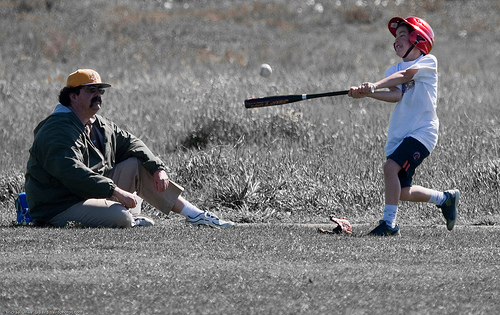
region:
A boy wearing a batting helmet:
[374, 11, 451, 100]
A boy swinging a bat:
[223, 8, 490, 160]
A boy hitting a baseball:
[234, 15, 451, 143]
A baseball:
[249, 48, 302, 95]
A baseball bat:
[217, 85, 390, 145]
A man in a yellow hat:
[44, 45, 174, 171]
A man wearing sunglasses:
[38, 50, 166, 164]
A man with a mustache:
[35, 40, 135, 148]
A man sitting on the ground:
[15, 47, 247, 288]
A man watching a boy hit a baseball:
[29, 2, 476, 274]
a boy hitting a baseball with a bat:
[242, 15, 461, 240]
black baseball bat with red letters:
[241, 82, 377, 110]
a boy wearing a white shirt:
[362, 14, 460, 239]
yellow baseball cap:
[64, 67, 112, 89]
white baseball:
[256, 62, 272, 78]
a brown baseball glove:
[315, 211, 351, 238]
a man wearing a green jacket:
[22, 67, 237, 230]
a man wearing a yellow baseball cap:
[23, 66, 235, 229]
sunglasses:
[82, 84, 104, 96]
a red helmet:
[384, 14, 435, 57]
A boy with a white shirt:
[291, 25, 485, 247]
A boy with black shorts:
[305, 6, 490, 252]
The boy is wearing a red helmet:
[315, 0, 464, 260]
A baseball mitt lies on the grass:
[293, 198, 388, 250]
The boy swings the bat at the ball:
[214, 11, 476, 262]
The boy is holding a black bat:
[231, 17, 474, 252]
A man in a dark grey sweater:
[5, 50, 245, 263]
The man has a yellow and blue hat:
[18, 53, 205, 240]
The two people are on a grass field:
[25, 16, 495, 291]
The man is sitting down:
[24, 59, 251, 250]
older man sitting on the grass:
[25, 67, 242, 232]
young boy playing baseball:
[241, 12, 459, 247]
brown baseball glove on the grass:
[310, 211, 359, 242]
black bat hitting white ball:
[240, 59, 377, 112]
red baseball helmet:
[385, 14, 435, 67]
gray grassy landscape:
[215, 131, 344, 201]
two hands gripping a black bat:
[241, 82, 388, 111]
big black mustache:
[80, 87, 109, 114]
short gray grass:
[178, 252, 293, 311]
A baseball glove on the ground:
[314, 208, 358, 244]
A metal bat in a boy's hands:
[239, 71, 365, 119]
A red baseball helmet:
[379, 6, 437, 64]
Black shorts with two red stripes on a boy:
[388, 133, 431, 194]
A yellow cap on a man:
[60, 62, 113, 93]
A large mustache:
[85, 94, 115, 113]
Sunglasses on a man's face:
[80, 84, 115, 99]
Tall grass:
[140, 56, 225, 134]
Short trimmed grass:
[153, 240, 297, 293]